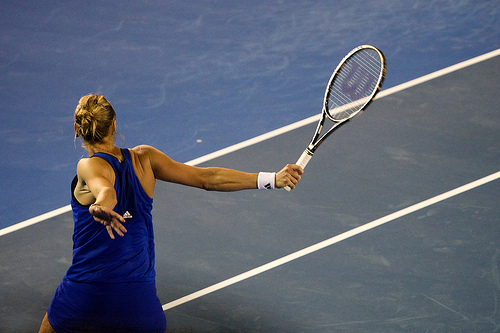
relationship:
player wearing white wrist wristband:
[62, 76, 189, 323] [255, 171, 278, 191]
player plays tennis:
[32, 93, 304, 333] [32, 34, 399, 332]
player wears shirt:
[32, 93, 304, 333] [52, 146, 164, 296]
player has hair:
[32, 93, 304, 333] [70, 103, 113, 137]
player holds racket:
[32, 93, 304, 333] [279, 39, 389, 197]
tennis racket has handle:
[275, 37, 395, 197] [279, 141, 320, 195]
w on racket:
[337, 52, 380, 106] [279, 39, 389, 197]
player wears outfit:
[32, 93, 304, 333] [41, 146, 173, 329]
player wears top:
[32, 93, 304, 333] [55, 144, 164, 302]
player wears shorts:
[32, 93, 304, 333] [41, 274, 170, 332]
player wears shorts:
[32, 93, 304, 333] [37, 277, 175, 331]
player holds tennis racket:
[32, 93, 304, 333] [281, 34, 390, 201]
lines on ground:
[342, 177, 496, 242] [328, 137, 495, 327]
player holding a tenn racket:
[32, 93, 304, 333] [279, 39, 389, 197]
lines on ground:
[6, 44, 484, 294] [2, 1, 498, 331]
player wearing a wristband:
[32, 93, 304, 333] [255, 171, 278, 191]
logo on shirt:
[117, 208, 137, 226] [61, 144, 161, 285]